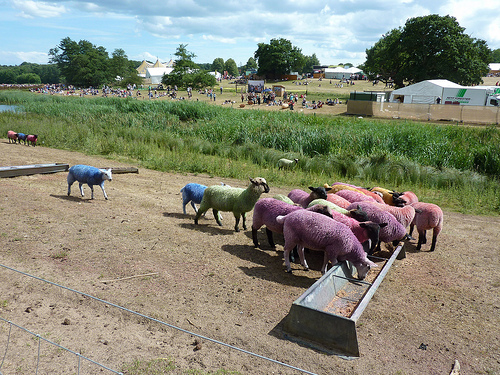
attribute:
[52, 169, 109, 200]
sheep — blue, rear, group, green, eating, walking, pink, colored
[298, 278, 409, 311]
trough — part, metal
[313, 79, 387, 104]
truck — green, white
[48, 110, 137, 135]
grass — green, dead, tall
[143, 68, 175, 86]
tent — white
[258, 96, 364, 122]
fence — metal